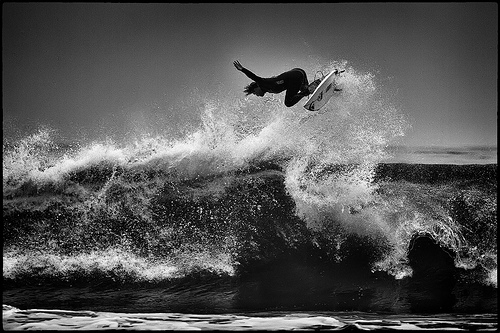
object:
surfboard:
[303, 64, 345, 113]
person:
[228, 55, 325, 112]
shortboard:
[302, 64, 346, 109]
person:
[230, 56, 324, 106]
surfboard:
[299, 61, 347, 113]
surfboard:
[304, 69, 345, 111]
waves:
[58, 135, 203, 180]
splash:
[323, 71, 395, 166]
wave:
[132, 127, 493, 262]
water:
[0, 162, 496, 332]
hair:
[241, 85, 254, 96]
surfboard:
[313, 78, 330, 100]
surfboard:
[302, 66, 349, 115]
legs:
[282, 67, 326, 108]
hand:
[229, 52, 244, 74]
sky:
[0, 0, 495, 151]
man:
[234, 63, 326, 108]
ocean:
[2, 146, 497, 331]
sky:
[15, 7, 491, 190]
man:
[228, 64, 355, 120]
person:
[232, 57, 319, 108]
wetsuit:
[239, 62, 312, 110]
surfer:
[230, 58, 319, 107]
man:
[227, 58, 322, 108]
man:
[232, 56, 322, 106]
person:
[229, 54, 313, 105]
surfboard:
[305, 77, 350, 113]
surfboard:
[292, 59, 346, 126]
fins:
[301, 62, 346, 114]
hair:
[240, 78, 267, 95]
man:
[221, 48, 321, 109]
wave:
[7, 137, 493, 308]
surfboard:
[302, 69, 357, 115]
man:
[243, 53, 347, 128]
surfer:
[212, 38, 402, 143]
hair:
[238, 80, 264, 107]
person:
[234, 61, 324, 106]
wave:
[56, 147, 495, 275]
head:
[238, 46, 274, 116]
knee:
[283, 96, 298, 107]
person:
[205, 60, 349, 115]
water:
[267, 227, 359, 300]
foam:
[146, 121, 378, 201]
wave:
[3, 138, 499, 328]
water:
[0, 60, 496, 330]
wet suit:
[243, 67, 307, 107]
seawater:
[34, 157, 497, 330]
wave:
[273, 126, 488, 264]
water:
[268, 279, 310, 294]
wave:
[3, 140, 380, 282]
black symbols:
[318, 84, 333, 104]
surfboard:
[302, 62, 352, 114]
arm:
[231, 58, 269, 84]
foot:
[304, 76, 323, 95]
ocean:
[0, 164, 498, 330]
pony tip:
[298, 96, 313, 111]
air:
[32, 15, 480, 109]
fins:
[322, 62, 382, 122]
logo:
[295, 91, 372, 125]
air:
[53, 24, 373, 103]